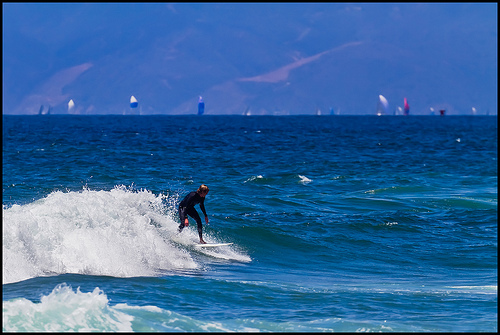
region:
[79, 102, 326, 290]
a man on a surfboard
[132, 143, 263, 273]
a man surfboarding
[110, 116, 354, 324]
a man surfing a wave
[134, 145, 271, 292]
a man riding a wave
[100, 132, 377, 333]
a man riding a surfboard on water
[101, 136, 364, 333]
a man on the water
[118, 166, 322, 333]
a man on blue water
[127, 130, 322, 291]
a surfer on water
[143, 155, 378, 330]
a surfer on the water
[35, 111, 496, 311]
a body of blue water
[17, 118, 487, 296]
surfer in blue ocean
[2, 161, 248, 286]
thick curve of white water behind surfer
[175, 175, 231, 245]
surfer leaning forward on board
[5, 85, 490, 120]
blue, white and red sails on horizon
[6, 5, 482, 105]
sky with angled clouds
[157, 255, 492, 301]
white line across ocean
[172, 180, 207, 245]
surfer wearing black wet suit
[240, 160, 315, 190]
short wave with white edges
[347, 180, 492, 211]
long green curves on water surface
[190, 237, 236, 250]
front end of white surfboard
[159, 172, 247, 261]
a surfer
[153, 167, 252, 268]
a person surfing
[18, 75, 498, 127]
sailboats in the distance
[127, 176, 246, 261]
a man is surfing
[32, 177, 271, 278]
the surfer rides a wave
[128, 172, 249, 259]
the man is standing on a surfboard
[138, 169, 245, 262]
the surfer is wearing a black wet suit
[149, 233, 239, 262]
the surfboard is white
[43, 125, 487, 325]
a man surfs in the ocean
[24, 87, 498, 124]
boats are seen on the horizon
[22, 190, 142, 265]
The white water is behind the surfer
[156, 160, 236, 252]
The surfer is on the water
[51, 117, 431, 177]
The ocean water is blue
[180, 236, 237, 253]
The surfboard is the color white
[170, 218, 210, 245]
The legs on the surfer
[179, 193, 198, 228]
The arm of the surfer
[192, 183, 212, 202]
The head of the surfer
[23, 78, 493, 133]
The boats are very far in the ocean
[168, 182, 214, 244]
The surfer is wearing a wet suit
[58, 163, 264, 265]
The surfer is wearing a small wave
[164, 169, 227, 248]
man surfing in ocean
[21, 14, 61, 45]
white clouds in blue sky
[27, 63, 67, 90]
white clouds in blue sky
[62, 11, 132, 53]
white clouds in blue sky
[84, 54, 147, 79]
white clouds in blue sky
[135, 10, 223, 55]
white clouds in blue sky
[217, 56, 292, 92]
white clouds in blue sky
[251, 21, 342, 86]
white clouds in blue sky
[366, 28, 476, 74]
white clouds in blue sky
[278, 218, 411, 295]
blue ocean